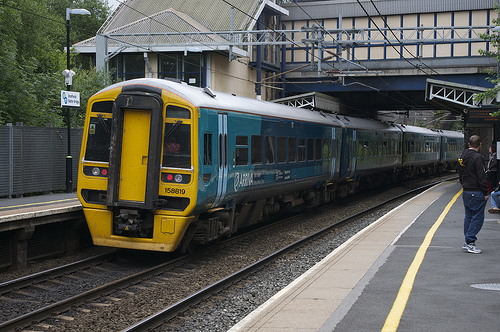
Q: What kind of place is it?
A: It is a station.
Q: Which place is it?
A: It is a station.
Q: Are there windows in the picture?
A: Yes, there is a window.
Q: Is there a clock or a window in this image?
A: Yes, there is a window.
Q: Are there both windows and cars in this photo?
A: No, there is a window but no cars.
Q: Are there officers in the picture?
A: No, there are no officers.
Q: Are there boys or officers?
A: No, there are no officers or boys.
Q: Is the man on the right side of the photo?
A: Yes, the man is on the right of the image.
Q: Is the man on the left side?
A: No, the man is on the right of the image.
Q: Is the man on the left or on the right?
A: The man is on the right of the image.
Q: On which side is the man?
A: The man is on the right of the image.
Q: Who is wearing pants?
A: The man is wearing pants.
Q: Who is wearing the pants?
A: The man is wearing pants.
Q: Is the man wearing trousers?
A: Yes, the man is wearing trousers.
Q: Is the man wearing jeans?
A: No, the man is wearing trousers.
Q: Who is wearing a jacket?
A: The man is wearing a jacket.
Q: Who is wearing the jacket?
A: The man is wearing a jacket.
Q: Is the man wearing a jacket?
A: Yes, the man is wearing a jacket.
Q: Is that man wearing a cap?
A: No, the man is wearing a jacket.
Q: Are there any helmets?
A: No, there are no helmets.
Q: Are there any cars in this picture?
A: No, there are no cars.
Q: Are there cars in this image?
A: No, there are no cars.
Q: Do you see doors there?
A: Yes, there is a door.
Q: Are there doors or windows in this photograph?
A: Yes, there is a door.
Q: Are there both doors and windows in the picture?
A: Yes, there are both a door and windows.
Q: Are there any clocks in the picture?
A: No, there are no clocks.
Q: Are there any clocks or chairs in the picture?
A: No, there are no clocks or chairs.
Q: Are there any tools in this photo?
A: No, there are no tools.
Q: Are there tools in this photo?
A: No, there are no tools.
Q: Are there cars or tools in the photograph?
A: No, there are no tools or cars.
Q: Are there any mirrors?
A: No, there are no mirrors.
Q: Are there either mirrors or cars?
A: No, there are no mirrors or cars.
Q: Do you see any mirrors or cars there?
A: No, there are no mirrors or cars.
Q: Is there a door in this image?
A: Yes, there is a door.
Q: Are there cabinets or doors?
A: Yes, there is a door.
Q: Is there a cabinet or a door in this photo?
A: Yes, there is a door.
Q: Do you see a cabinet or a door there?
A: Yes, there is a door.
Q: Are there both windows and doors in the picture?
A: Yes, there are both a door and a window.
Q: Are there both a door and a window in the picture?
A: Yes, there are both a door and a window.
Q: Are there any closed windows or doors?
A: Yes, there is a closed door.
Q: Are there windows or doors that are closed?
A: Yes, the door is closed.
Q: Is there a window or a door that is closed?
A: Yes, the door is closed.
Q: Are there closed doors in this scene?
A: Yes, there is a closed door.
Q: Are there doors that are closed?
A: Yes, there is a closed door.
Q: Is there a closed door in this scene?
A: Yes, there is a closed door.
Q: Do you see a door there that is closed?
A: Yes, there is a door that is closed.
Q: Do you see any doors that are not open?
A: Yes, there is an closed door.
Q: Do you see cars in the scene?
A: No, there are no cars.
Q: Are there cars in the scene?
A: No, there are no cars.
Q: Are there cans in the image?
A: No, there are no cans.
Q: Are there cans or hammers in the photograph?
A: No, there are no cans or hammers.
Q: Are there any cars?
A: No, there are no cars.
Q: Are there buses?
A: No, there are no buses.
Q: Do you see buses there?
A: No, there are no buses.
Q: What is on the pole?
A: The sign is on the pole.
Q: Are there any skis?
A: No, there are no skis.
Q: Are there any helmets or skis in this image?
A: No, there are no skis or helmets.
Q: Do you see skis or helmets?
A: No, there are no skis or helmets.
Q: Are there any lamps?
A: Yes, there is a lamp.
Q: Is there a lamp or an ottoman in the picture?
A: Yes, there is a lamp.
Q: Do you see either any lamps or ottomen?
A: Yes, there is a lamp.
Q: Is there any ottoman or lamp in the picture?
A: Yes, there is a lamp.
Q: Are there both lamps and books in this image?
A: No, there is a lamp but no books.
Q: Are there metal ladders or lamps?
A: Yes, there is a metal lamp.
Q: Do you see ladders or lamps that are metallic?
A: Yes, the lamp is metallic.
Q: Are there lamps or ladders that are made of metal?
A: Yes, the lamp is made of metal.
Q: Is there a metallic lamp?
A: Yes, there is a metal lamp.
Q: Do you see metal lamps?
A: Yes, there is a metal lamp.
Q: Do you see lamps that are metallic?
A: Yes, there is a lamp that is metallic.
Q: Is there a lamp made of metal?
A: Yes, there is a lamp that is made of metal.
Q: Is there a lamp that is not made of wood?
A: Yes, there is a lamp that is made of metal.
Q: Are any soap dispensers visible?
A: No, there are no soap dispensers.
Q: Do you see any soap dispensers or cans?
A: No, there are no soap dispensers or cans.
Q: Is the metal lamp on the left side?
A: Yes, the lamp is on the left of the image.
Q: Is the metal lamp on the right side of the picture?
A: No, the lamp is on the left of the image.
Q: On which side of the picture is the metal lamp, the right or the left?
A: The lamp is on the left of the image.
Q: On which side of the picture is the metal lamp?
A: The lamp is on the left of the image.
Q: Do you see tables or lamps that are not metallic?
A: No, there is a lamp but it is metallic.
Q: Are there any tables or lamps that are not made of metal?
A: No, there is a lamp but it is made of metal.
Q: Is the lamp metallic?
A: Yes, the lamp is metallic.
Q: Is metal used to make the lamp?
A: Yes, the lamp is made of metal.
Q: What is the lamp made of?
A: The lamp is made of metal.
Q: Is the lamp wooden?
A: No, the lamp is metallic.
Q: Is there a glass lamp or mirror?
A: No, there is a lamp but it is metallic.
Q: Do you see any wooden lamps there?
A: No, there is a lamp but it is metallic.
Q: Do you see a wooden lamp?
A: No, there is a lamp but it is metallic.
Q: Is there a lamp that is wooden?
A: No, there is a lamp but it is metallic.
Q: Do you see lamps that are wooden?
A: No, there is a lamp but it is metallic.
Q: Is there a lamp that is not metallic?
A: No, there is a lamp but it is metallic.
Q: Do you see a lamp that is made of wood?
A: No, there is a lamp but it is made of metal.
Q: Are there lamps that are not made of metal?
A: No, there is a lamp but it is made of metal.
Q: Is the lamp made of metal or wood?
A: The lamp is made of metal.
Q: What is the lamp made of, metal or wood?
A: The lamp is made of metal.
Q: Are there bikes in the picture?
A: No, there are no bikes.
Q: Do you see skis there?
A: No, there are no skis.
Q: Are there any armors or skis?
A: No, there are no skis or armors.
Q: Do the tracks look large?
A: Yes, the tracks are large.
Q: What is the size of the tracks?
A: The tracks are large.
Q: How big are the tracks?
A: The tracks are large.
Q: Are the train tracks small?
A: No, the train tracks are large.